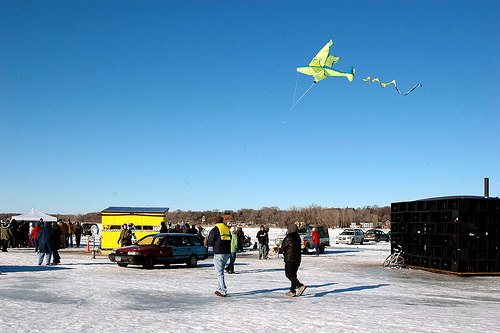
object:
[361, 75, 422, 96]
kite tail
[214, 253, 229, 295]
trouser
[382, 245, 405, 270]
bicycle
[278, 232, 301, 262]
jacket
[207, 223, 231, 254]
jacket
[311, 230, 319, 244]
jacket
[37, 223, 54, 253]
jacket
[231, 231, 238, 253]
jacket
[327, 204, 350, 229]
plants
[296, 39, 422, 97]
kite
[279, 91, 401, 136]
floor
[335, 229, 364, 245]
car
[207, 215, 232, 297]
man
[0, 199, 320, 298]
people walking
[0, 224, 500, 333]
snow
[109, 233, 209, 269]
car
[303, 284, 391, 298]
shadow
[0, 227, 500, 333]
ground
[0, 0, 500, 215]
sky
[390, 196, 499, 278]
box